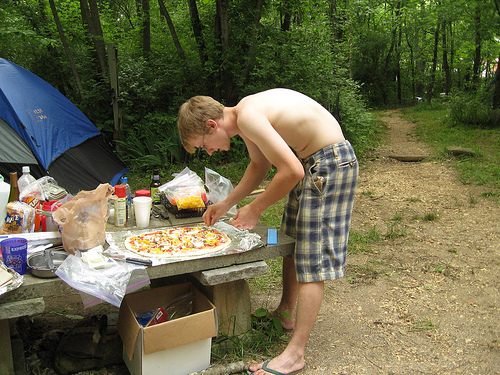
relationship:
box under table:
[105, 282, 199, 370] [0, 205, 291, 361]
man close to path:
[177, 85, 358, 375] [352, 101, 499, 374]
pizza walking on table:
[142, 225, 232, 259] [0, 167, 274, 320]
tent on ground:
[0, 60, 122, 201] [9, 106, 497, 370]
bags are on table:
[57, 247, 152, 309] [1, 197, 303, 358]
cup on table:
[1, 236, 31, 275] [0, 202, 297, 374]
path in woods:
[352, 101, 499, 374] [3, 1, 498, 178]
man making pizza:
[170, 85, 369, 373] [126, 225, 232, 258]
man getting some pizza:
[177, 85, 358, 375] [122, 226, 231, 258]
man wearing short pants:
[177, 85, 358, 375] [269, 147, 346, 232]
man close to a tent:
[177, 85, 358, 375] [1, 55, 106, 182]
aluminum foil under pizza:
[103, 217, 264, 265] [121, 223, 231, 258]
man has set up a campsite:
[177, 85, 358, 375] [0, 51, 307, 373]